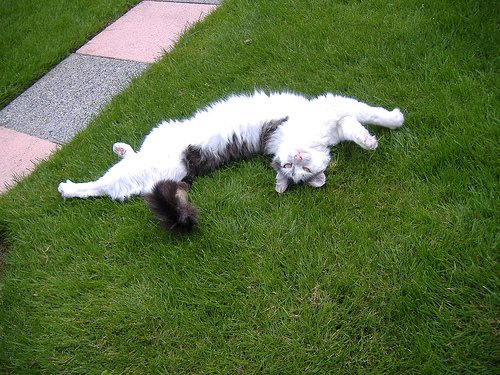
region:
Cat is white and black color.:
[86, 73, 378, 223]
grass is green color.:
[206, 261, 435, 332]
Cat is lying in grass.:
[131, 94, 364, 226]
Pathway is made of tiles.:
[52, 13, 159, 116]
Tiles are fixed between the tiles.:
[24, 23, 216, 100]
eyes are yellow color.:
[269, 154, 327, 181]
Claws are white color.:
[355, 98, 407, 153]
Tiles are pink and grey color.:
[11, 30, 176, 131]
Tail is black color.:
[150, 171, 209, 237]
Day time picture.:
[18, 20, 483, 367]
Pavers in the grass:
[11, 2, 206, 123]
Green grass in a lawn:
[222, 202, 479, 353]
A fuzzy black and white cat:
[140, 75, 420, 240]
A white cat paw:
[375, 95, 420, 130]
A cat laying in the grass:
[164, 75, 411, 214]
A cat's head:
[263, 141, 339, 197]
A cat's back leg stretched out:
[54, 158, 147, 215]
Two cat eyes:
[281, 157, 317, 178]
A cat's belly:
[163, 85, 290, 154]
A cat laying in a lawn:
[155, 50, 467, 295]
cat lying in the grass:
[43, 71, 408, 268]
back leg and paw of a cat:
[49, 165, 115, 207]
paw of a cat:
[110, 132, 137, 159]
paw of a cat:
[54, 175, 79, 200]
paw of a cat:
[387, 103, 408, 133]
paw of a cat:
[355, 128, 382, 153]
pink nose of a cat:
[293, 148, 303, 162]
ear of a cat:
[269, 173, 296, 197]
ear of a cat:
[307, 168, 327, 190]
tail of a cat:
[145, 164, 199, 239]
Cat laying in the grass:
[60, 81, 475, 268]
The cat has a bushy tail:
[139, 167, 226, 266]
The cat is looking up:
[264, 120, 329, 214]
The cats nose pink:
[285, 134, 315, 174]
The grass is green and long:
[213, 193, 321, 253]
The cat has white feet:
[327, 85, 416, 172]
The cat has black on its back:
[174, 126, 276, 173]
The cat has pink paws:
[107, 129, 127, 153]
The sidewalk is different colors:
[50, 12, 181, 160]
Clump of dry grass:
[301, 276, 325, 298]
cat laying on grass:
[106, 78, 375, 247]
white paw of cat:
[366, 97, 400, 133]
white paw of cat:
[346, 125, 381, 158]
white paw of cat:
[56, 174, 94, 207]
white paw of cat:
[108, 137, 128, 164]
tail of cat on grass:
[142, 176, 195, 239]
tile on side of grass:
[28, 53, 129, 147]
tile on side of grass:
[88, 3, 190, 55]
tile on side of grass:
[0, 127, 27, 187]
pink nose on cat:
[293, 150, 307, 165]